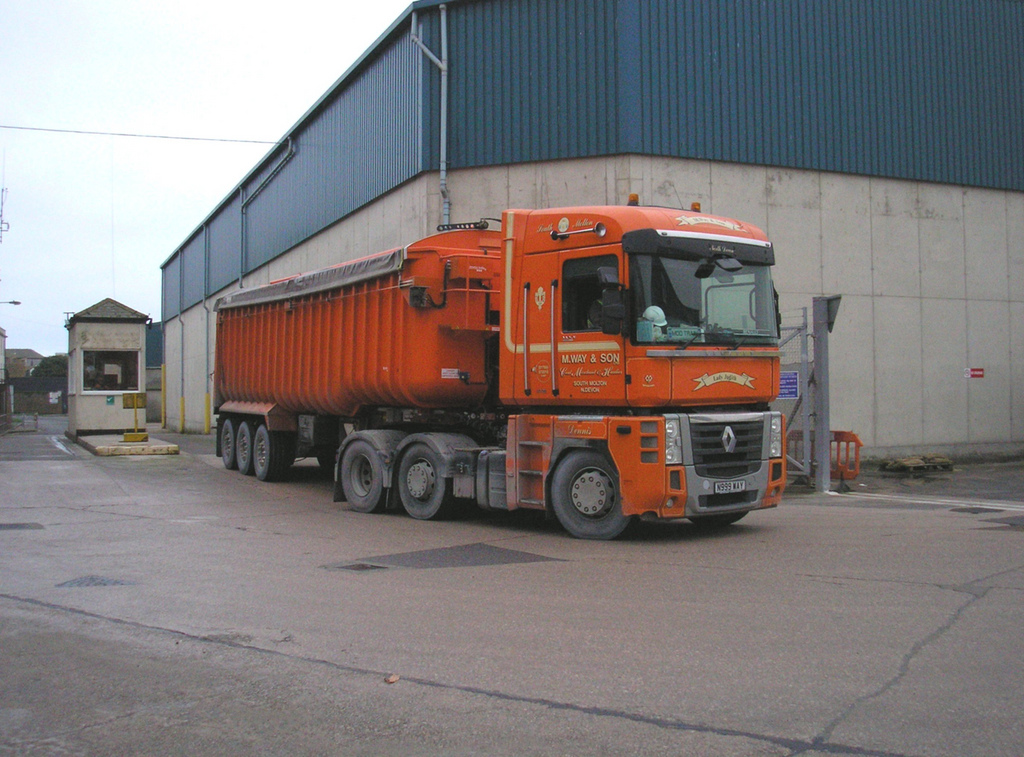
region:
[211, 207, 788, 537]
Orange truck near a warehouse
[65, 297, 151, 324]
The roof of a ticket booth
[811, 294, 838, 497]
A metal fence pole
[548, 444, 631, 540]
Front left tire on an orange truck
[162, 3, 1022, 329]
The blue roof of a warehouse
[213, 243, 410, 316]
Tarp covering the bed of a truck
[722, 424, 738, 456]
Car manufacturer logo on an orange truck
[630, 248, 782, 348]
Windshield of the orange truck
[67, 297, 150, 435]
Ticket booth at the entrance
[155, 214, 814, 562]
large orange and gray truck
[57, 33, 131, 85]
white clouds in blue sky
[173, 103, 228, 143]
white clouds in blue sky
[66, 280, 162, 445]
small tan and brown buildihng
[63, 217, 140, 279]
white clouds in blue sky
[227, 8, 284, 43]
white clouds in blue sky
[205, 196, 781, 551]
semi truck next to a building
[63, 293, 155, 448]
ticket booth next to building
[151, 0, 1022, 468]
building with blue trim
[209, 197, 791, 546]
orange semi truck on concrete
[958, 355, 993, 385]
red sign on the side of a building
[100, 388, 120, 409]
green sign on building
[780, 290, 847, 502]
gate attached to building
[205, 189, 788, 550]
semi truck parked next to a building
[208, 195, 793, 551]
orange semi with multiple tires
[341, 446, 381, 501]
tire attached to truck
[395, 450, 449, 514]
tire attached to truck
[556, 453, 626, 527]
tire attached to truck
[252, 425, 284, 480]
tire attached to truck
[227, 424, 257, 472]
tire attached to truck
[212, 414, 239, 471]
tire attached to truck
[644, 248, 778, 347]
window attached to truck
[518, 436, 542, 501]
step under truck door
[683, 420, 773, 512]
grill on front end of truck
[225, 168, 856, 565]
large orange truck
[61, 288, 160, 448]
small ran and brown structure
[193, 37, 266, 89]
white clouds in blue sky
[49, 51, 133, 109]
white clouds in blue sky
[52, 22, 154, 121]
white clouds in blue sky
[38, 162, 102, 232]
white clouds in blue sky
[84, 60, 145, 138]
white clouds in blue sky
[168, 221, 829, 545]
Orange truck in a lot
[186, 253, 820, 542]
Large truck in a lot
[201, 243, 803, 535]
Large orange truck in a lot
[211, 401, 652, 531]
Many wheels on a truck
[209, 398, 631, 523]
Many wheels on a large truck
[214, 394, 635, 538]
Many wheels on a large orange truck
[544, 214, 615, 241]
Air horn on large orange truck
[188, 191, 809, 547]
truck parked in front of building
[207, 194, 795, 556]
parked truck is orange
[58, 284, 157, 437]
small building by building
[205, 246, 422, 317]
tarp covering back of truck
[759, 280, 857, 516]
gate behind orange truck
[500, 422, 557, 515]
step ladder beneath truck door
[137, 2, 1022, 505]
large truck behind truck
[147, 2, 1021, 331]
large metal roof on building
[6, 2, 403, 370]
sky is partly cloudy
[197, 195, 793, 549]
a large orange truck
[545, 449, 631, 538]
a large black truck tire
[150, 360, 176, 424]
a tall yellow pole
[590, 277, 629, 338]
a black rear view mirror